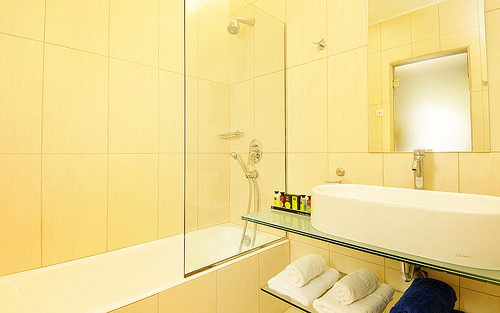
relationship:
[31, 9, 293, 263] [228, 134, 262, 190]
shower has faucet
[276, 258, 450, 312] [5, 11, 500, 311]
towels in bathroom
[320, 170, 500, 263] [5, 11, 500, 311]
sink in bathroom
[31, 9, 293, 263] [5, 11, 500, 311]
shower in bathroom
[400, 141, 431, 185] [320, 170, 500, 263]
tap over sink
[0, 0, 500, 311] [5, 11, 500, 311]
bathroom in bathroom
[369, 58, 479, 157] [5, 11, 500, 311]
mirror in bathroom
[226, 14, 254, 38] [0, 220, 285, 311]
shower head in tub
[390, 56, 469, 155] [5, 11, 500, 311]
doorway to bathroom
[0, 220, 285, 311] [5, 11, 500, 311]
tub in bathroom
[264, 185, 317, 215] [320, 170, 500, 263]
items on sink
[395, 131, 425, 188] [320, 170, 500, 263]
faucet in sink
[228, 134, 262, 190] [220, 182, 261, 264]
shower head has extender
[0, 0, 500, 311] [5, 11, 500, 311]
bathroom a bathroom